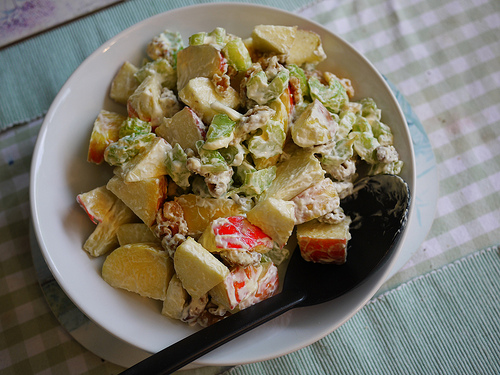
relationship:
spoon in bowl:
[118, 171, 410, 374] [30, 2, 417, 366]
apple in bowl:
[296, 215, 352, 265] [30, 2, 417, 366]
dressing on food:
[76, 24, 404, 327] [76, 26, 403, 328]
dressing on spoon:
[340, 173, 410, 243] [118, 171, 410, 374]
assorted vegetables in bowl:
[77, 24, 403, 328] [30, 2, 417, 366]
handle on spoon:
[118, 293, 302, 374] [118, 171, 410, 374]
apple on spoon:
[296, 215, 352, 265] [118, 171, 410, 374]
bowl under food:
[30, 2, 417, 366] [76, 26, 403, 328]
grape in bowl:
[223, 41, 252, 74] [30, 2, 417, 366]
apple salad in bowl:
[77, 25, 404, 327] [30, 2, 417, 366]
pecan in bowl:
[157, 198, 189, 260] [30, 2, 417, 366]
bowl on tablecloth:
[30, 2, 417, 366] [0, 1, 499, 374]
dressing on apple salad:
[76, 24, 404, 327] [77, 25, 404, 327]